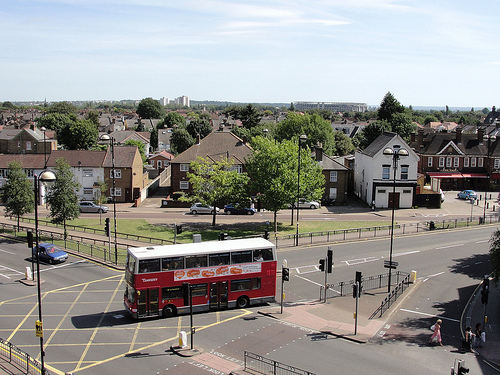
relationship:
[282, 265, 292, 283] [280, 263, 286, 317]
streetlight on pole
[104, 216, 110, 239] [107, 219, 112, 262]
streetlight on pole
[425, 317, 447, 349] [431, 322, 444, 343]
woman wearing dress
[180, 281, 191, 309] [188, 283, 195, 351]
streetlight on pole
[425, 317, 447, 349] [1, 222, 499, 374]
woman crossing street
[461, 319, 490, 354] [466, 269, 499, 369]
people on sidewalk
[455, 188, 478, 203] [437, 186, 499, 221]
car in parking lot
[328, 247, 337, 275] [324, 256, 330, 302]
streetlight on pole